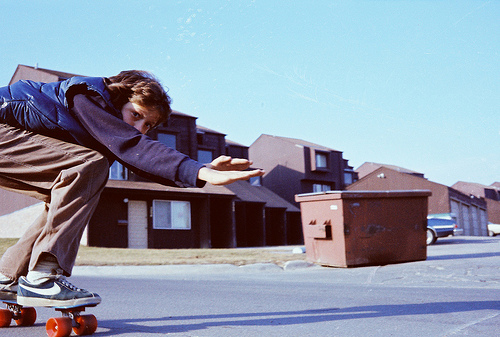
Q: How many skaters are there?
A: One.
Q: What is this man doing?
A: Skating.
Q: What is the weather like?
A: Sunny.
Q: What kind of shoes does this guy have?
A: Nikes.